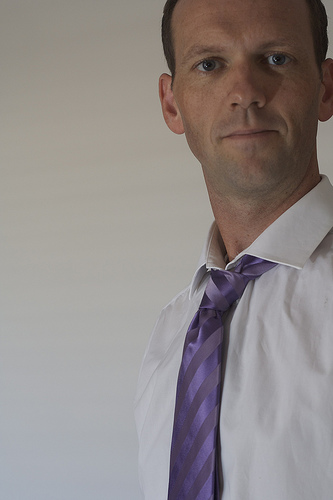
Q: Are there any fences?
A: No, there are no fences.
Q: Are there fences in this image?
A: No, there are no fences.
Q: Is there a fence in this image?
A: No, there are no fences.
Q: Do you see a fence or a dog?
A: No, there are no fences or dogs.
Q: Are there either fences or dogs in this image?
A: No, there are no fences or dogs.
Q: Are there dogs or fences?
A: No, there are no fences or dogs.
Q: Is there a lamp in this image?
A: No, there are no lamps.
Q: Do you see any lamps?
A: No, there are no lamps.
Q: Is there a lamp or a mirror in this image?
A: No, there are no lamps or mirrors.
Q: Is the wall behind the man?
A: Yes, the wall is behind the man.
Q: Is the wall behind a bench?
A: No, the wall is behind the man.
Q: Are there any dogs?
A: No, there are no dogs.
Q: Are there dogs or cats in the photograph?
A: No, there are no dogs or cats.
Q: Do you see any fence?
A: No, there are no fences.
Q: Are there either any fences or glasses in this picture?
A: No, there are no fences or glasses.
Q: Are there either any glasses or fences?
A: No, there are no fences or glasses.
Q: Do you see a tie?
A: Yes, there is a tie.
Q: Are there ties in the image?
A: Yes, there is a tie.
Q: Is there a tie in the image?
A: Yes, there is a tie.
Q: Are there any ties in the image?
A: Yes, there is a tie.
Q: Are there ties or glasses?
A: Yes, there is a tie.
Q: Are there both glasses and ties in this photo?
A: No, there is a tie but no glasses.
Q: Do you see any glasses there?
A: No, there are no glasses.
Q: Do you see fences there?
A: No, there are no fences.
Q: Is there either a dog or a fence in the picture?
A: No, there are no fences or dogs.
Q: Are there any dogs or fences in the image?
A: No, there are no fences or dogs.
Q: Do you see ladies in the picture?
A: No, there are no ladies.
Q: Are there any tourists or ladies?
A: No, there are no ladies or tourists.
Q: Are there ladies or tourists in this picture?
A: No, there are no ladies or tourists.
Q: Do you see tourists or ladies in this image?
A: No, there are no ladies or tourists.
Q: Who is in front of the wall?
A: The man is in front of the wall.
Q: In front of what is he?
A: The man is in front of the wall.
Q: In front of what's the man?
A: The man is in front of the wall.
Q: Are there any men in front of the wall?
A: Yes, there is a man in front of the wall.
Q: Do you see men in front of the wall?
A: Yes, there is a man in front of the wall.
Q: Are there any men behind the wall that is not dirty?
A: No, the man is in front of the wall.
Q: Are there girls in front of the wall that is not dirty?
A: No, there is a man in front of the wall.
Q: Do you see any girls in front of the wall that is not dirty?
A: No, there is a man in front of the wall.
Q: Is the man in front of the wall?
A: Yes, the man is in front of the wall.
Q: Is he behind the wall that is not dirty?
A: No, the man is in front of the wall.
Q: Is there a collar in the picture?
A: Yes, there is a collar.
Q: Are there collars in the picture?
A: Yes, there is a collar.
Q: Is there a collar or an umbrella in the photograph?
A: Yes, there is a collar.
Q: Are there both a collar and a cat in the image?
A: No, there is a collar but no cats.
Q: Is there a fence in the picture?
A: No, there are no fences.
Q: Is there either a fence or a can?
A: No, there are no fences or cans.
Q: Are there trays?
A: No, there are no trays.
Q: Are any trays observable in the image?
A: No, there are no trays.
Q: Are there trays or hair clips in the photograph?
A: No, there are no trays or hair clips.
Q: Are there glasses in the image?
A: No, there are no glasses.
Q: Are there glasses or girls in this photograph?
A: No, there are no glasses or girls.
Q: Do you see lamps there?
A: No, there are no lamps.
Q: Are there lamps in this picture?
A: No, there are no lamps.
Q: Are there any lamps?
A: No, there are no lamps.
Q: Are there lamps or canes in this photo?
A: No, there are no lamps or canes.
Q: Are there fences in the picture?
A: No, there are no fences.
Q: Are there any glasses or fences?
A: No, there are no fences or glasses.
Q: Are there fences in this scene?
A: No, there are no fences.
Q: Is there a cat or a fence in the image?
A: No, there are no fences or cats.